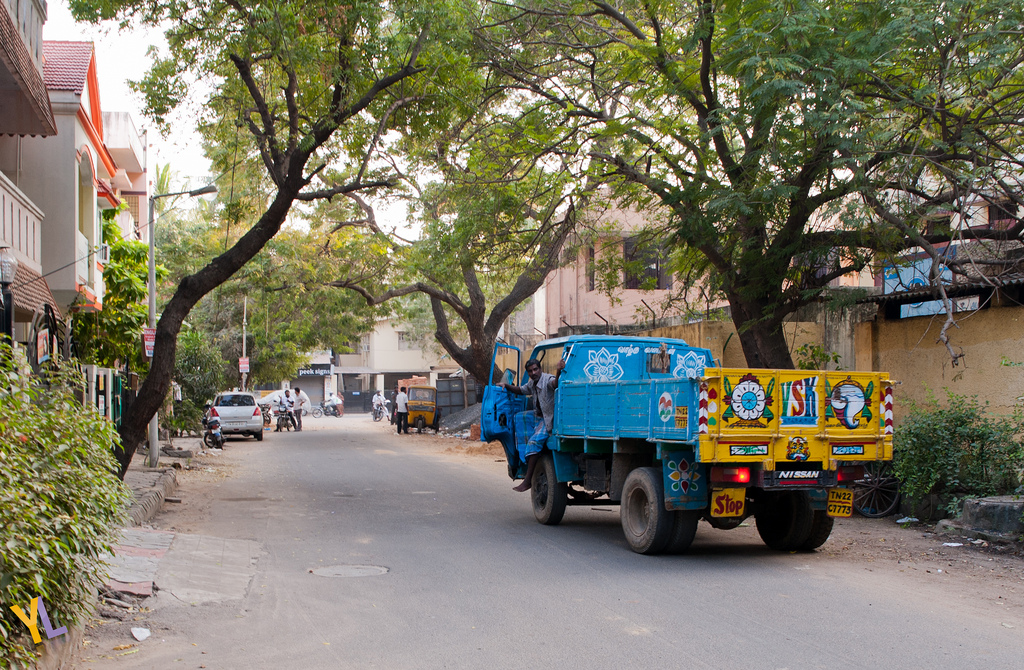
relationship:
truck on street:
[474, 333, 929, 518] [455, 314, 917, 567]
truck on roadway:
[474, 333, 929, 518] [461, 320, 905, 561]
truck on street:
[474, 333, 930, 518] [133, 333, 930, 613]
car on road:
[199, 374, 279, 438] [199, 374, 557, 668]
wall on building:
[865, 290, 1018, 407] [865, 290, 1018, 407]